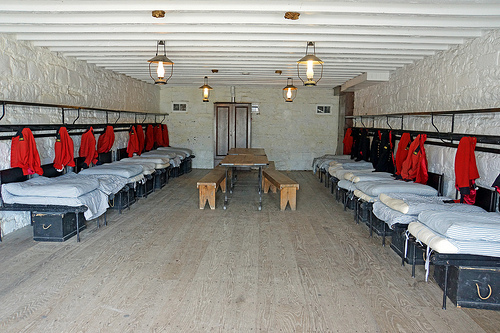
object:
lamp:
[146, 42, 176, 86]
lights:
[295, 42, 327, 86]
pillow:
[7, 174, 98, 197]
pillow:
[353, 179, 435, 197]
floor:
[0, 170, 498, 332]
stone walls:
[351, 30, 500, 203]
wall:
[0, 34, 160, 239]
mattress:
[0, 180, 103, 207]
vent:
[340, 70, 390, 91]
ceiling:
[0, 0, 500, 87]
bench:
[194, 165, 234, 214]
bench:
[258, 169, 300, 212]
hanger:
[0, 101, 169, 134]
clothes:
[11, 126, 44, 176]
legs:
[206, 185, 215, 210]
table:
[218, 154, 268, 211]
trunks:
[433, 260, 500, 310]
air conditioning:
[172, 104, 187, 112]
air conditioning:
[313, 103, 333, 115]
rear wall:
[161, 87, 342, 170]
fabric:
[53, 127, 77, 173]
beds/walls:
[0, 167, 111, 242]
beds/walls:
[367, 184, 496, 248]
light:
[282, 77, 300, 103]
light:
[198, 77, 216, 102]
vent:
[314, 103, 334, 115]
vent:
[171, 104, 189, 112]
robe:
[452, 135, 480, 206]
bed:
[398, 211, 497, 309]